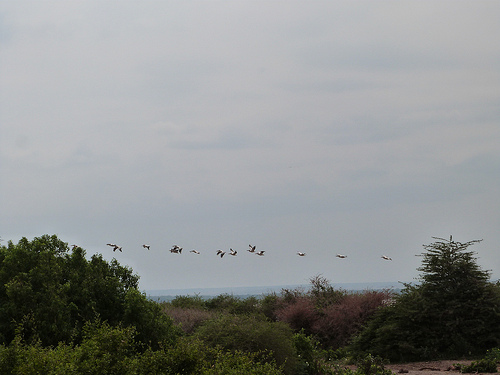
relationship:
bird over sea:
[381, 253, 393, 261] [143, 275, 499, 305]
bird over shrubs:
[381, 253, 393, 261] [157, 275, 400, 340]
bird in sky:
[336, 252, 347, 258] [0, 0, 500, 303]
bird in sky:
[296, 250, 306, 257] [0, 0, 500, 303]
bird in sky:
[256, 249, 265, 257] [0, 0, 500, 303]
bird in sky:
[107, 242, 122, 252] [0, 0, 500, 303]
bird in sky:
[248, 244, 256, 253] [0, 0, 500, 303]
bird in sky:
[229, 246, 237, 258] [0, 0, 500, 303]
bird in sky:
[215, 247, 225, 258] [0, 0, 500, 303]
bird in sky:
[191, 248, 201, 254] [0, 0, 500, 303]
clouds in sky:
[0, 0, 499, 229] [0, 0, 500, 303]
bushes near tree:
[271, 288, 389, 343] [0, 233, 139, 356]